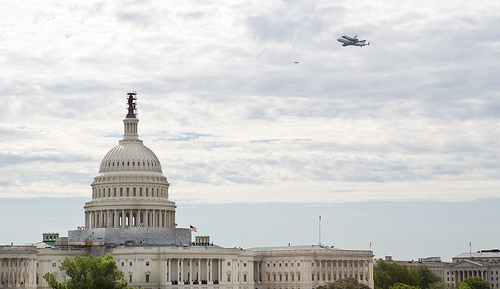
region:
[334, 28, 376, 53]
a plane in the sky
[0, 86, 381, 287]
The white house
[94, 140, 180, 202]
a large white dome roof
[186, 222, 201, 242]
the american flag in the wind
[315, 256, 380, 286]
a row of white pillars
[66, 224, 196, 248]
a white construction fence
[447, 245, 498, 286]
a distant white building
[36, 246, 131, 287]
the foliage of a tree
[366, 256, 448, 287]
a few wide trees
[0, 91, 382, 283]
The capital building of USA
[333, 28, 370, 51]
an airplane is flying in air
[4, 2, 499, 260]
sky is cloudy and overcast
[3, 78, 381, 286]
large building ornate in style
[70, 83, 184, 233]
large dome above building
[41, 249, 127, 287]
tree in front of building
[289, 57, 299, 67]
bird flying in the air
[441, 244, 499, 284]
small building to the right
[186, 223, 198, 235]
flag flying atop the building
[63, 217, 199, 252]
partition for construction on building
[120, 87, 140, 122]
towers and antennas on top of building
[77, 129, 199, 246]
this is the white house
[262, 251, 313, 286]
the wall is white in color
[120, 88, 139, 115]
this is an antennae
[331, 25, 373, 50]
this is a plane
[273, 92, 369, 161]
this is the sky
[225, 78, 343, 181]
the sky is white in color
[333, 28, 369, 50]
the plane is on air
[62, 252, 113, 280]
the leaves are green in color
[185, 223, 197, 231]
this is the flag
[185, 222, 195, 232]
the flag is red in color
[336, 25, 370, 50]
A large plane in the sky.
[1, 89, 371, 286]
A large white building.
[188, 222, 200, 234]
An american flag.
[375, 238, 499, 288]
A building in the background.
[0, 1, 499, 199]
Clouds in the sky.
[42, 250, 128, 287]
A large green tree.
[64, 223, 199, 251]
A construction area.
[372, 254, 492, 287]
A grouping of trees.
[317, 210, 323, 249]
A distant pole.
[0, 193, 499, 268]
An area of blue sky.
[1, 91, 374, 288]
the large building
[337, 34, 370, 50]
the airplane in the sky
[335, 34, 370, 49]
the flying airplane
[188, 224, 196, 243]
the american flag on the building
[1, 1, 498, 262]
the clouds in the sky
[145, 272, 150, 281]
the window on the building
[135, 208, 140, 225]
the column on the building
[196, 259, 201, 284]
the column on the building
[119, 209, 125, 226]
the column on the building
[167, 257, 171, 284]
the column on the building